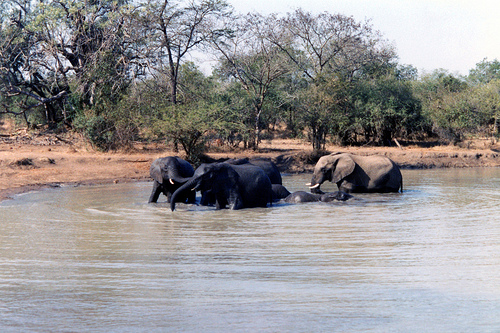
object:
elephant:
[305, 151, 405, 196]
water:
[3, 213, 500, 332]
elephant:
[170, 164, 275, 212]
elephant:
[147, 157, 193, 208]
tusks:
[310, 184, 320, 189]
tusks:
[306, 182, 311, 187]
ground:
[3, 156, 147, 197]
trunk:
[167, 175, 200, 212]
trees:
[0, 2, 499, 137]